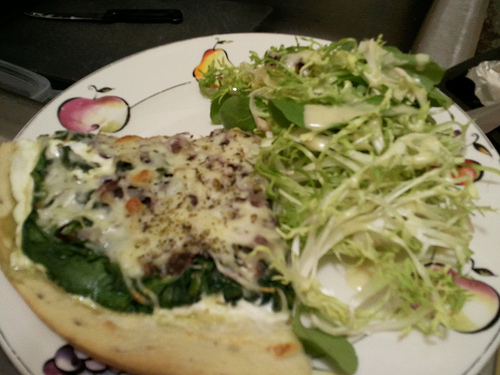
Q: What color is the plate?
A: White, yellow, and purple.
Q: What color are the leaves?
A: Green.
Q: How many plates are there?
A: One.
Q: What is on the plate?
A: The food.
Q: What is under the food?
A: The plate.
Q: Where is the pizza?
A: Next to the salad.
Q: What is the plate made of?
A: Porcelain.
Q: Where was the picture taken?
A: At a restaurant.